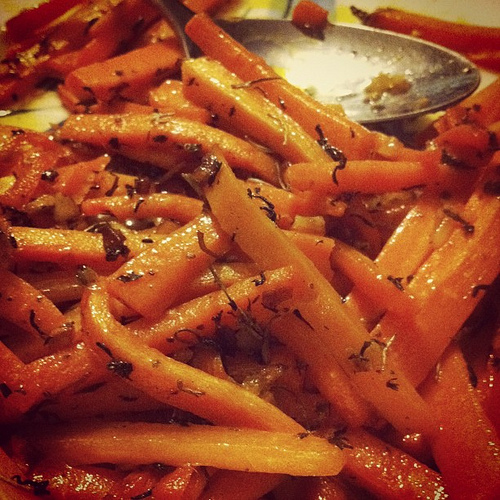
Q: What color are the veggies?
A: Orange.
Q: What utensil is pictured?
A: A spoon.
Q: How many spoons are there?
A: One.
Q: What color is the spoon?
A: Silver.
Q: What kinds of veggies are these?
A: Carrots.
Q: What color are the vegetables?
A: Orange.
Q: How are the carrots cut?
A: Sliced.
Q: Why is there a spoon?
A: For serving carrots.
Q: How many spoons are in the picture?
A: One.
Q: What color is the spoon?
A: Silver.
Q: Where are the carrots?
A: On a plate.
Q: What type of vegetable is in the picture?
A: Carrots.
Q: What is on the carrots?
A: Herbs.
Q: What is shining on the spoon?
A: Light.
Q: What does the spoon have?
A: Drops.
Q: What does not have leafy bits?
A: Carrot.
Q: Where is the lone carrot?
A: Near the spoon.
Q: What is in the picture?
A: Carrots.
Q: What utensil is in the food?
A: A spoon.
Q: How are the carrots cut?
A: Matchsticks.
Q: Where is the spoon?
A: In the food.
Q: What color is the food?
A: Orange.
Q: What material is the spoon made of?
A: Metal.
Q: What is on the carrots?
A: Seasoning.